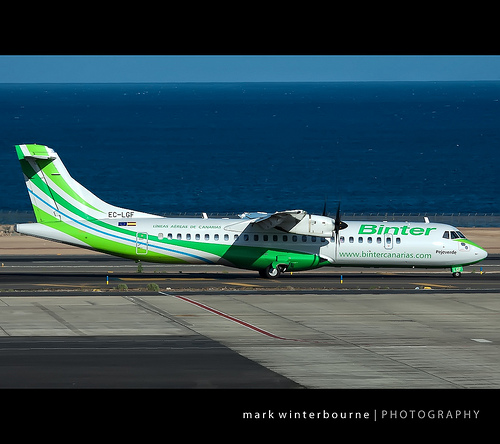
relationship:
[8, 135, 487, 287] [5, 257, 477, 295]
plane on runway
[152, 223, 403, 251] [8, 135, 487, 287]
windows along side of plane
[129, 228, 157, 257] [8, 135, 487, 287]
door on plane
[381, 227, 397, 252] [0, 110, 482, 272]
door on plane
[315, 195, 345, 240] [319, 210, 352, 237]
propellers on plane engine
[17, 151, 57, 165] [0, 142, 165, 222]
stabilizer on plane tail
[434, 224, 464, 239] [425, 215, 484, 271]
windows of cockpit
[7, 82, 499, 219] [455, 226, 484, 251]
water on side of airport runway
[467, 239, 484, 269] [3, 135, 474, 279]
nose of a airplane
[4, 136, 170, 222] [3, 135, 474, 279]
tail wing on airplane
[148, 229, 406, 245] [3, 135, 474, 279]
windows on a airplane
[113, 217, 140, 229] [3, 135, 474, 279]
flag painted on a airplane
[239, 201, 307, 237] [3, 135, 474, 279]
wing on a airplane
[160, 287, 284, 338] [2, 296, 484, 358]
line painted on a runway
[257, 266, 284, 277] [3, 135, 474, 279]
wheels on a airplane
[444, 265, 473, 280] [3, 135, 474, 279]
landing gear on a airplane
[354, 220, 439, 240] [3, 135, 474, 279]
letters painted on a airplane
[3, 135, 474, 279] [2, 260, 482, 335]
airplane on a tarmac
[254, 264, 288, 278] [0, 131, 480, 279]
landing gear of plane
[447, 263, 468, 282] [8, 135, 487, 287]
landing gear on plane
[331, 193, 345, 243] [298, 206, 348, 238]
propeller on right engine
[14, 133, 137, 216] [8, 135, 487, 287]
tail on plane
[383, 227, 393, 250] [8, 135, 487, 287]
front door on plane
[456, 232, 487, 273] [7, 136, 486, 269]
nose on plane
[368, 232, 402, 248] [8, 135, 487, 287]
windows on side of plane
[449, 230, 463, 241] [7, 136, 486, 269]
windshield on plane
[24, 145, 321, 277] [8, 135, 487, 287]
stripes on plane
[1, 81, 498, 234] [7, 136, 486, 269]
water on plane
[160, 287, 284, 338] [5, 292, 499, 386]
line on runway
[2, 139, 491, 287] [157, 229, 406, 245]
windows on plane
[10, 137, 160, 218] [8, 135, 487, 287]
tail on plane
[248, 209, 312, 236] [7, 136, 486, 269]
wing on plane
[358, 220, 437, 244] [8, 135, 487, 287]
binter on plane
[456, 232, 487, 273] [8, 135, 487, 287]
nose on plane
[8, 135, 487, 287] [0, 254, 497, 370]
plane on runway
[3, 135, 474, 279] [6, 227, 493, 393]
airplane on ground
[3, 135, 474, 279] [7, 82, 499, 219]
airplane by water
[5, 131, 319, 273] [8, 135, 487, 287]
stripes on plane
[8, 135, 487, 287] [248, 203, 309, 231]
plane shaded by wing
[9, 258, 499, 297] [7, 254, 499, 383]
strip of runway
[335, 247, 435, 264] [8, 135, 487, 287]
website url on plane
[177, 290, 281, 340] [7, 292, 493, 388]
line on ground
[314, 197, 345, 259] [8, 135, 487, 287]
propellers on plane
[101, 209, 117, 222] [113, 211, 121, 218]
letters separated by hyphen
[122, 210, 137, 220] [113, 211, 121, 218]
letters separated by hyphen